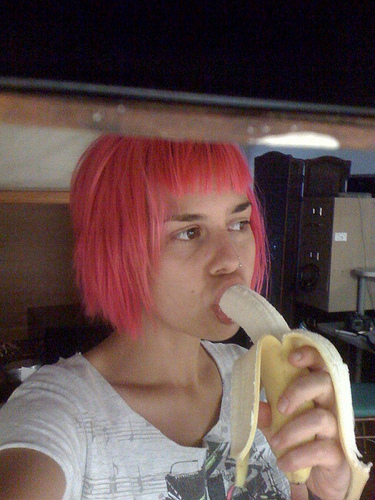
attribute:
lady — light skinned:
[2, 127, 348, 498]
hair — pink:
[55, 130, 278, 335]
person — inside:
[9, 126, 371, 498]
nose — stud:
[204, 227, 243, 273]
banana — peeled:
[212, 280, 374, 496]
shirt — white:
[3, 339, 286, 497]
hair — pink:
[67, 133, 274, 340]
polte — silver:
[356, 272, 368, 317]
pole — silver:
[356, 272, 366, 317]